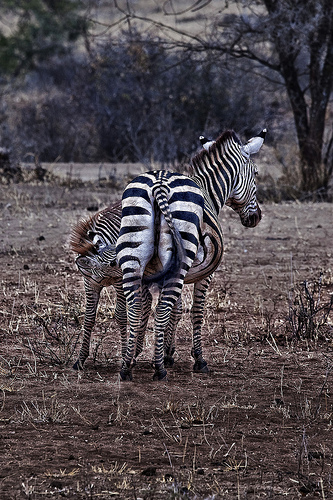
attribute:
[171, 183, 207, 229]
stripes — black , white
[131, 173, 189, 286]
tail — tall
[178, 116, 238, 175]
comb — on back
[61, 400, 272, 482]
dirt — brown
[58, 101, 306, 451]
zebra — standing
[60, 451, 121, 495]
bush — small patch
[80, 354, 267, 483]
ground — small patch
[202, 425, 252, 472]
bush — small patch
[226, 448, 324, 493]
bush — small patch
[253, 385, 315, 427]
bush — small patch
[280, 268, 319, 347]
bush — small patch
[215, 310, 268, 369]
bush — small patch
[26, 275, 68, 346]
brush — small, patch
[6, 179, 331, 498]
grassland — vast, barren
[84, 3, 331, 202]
tree — large, tall, leafless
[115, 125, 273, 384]
zebra — mother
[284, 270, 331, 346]
thistle — patch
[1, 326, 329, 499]
grass — dead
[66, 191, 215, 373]
zebra — young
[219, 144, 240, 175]
stripes — black, white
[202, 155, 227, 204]
stripes — black, white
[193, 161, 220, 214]
stripes — black, white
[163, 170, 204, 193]
stripes — black, white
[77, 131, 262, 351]
zebra — black, white, striped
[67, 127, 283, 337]
zebra — striped, black, white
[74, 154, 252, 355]
zebra — white, black, striped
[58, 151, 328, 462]
zebra — striped, white, black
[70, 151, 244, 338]
zebra — black, striped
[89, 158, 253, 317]
zebra — striped, black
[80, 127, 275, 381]
zebra — black, striped